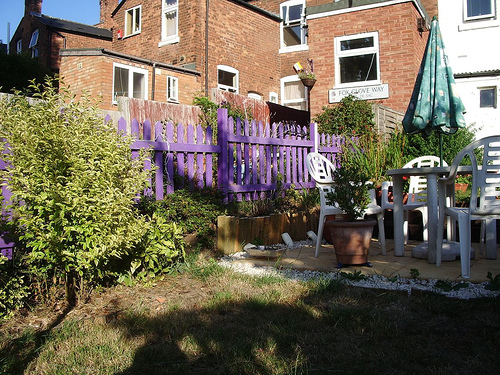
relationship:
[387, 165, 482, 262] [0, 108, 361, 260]
table near picket fence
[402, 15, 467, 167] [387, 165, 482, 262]
umbrella above table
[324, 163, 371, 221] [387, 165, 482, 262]
plant near table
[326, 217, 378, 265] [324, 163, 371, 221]
pot housing plant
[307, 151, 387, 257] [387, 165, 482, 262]
chair near table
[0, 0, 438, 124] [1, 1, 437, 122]
building made of red bricks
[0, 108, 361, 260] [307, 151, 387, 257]
picket fence behind chair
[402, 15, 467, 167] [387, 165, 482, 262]
umbrella on table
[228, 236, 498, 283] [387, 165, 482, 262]
slab under table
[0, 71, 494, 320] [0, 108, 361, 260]
shrubs near picket fence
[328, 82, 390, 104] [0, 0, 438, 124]
sign on building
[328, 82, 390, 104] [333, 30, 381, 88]
sign under window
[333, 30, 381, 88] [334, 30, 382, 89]
window has a white frame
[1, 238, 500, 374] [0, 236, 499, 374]
shadows on ground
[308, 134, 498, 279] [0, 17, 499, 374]
furniture in back yard